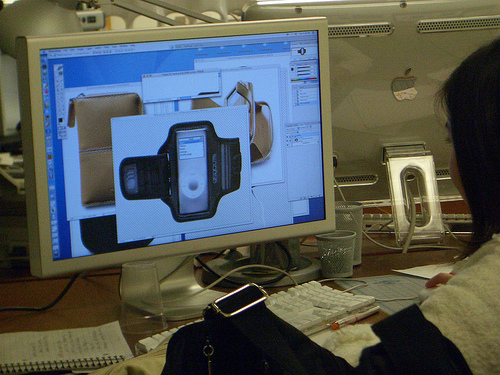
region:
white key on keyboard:
[318, 310, 330, 320]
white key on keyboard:
[327, 308, 341, 315]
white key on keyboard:
[331, 304, 343, 314]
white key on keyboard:
[298, 289, 310, 297]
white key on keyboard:
[308, 278, 320, 287]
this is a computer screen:
[29, 22, 438, 304]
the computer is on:
[42, 67, 250, 216]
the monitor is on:
[30, 44, 270, 245]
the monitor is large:
[37, 38, 316, 247]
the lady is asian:
[398, 87, 498, 253]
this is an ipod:
[102, 97, 253, 209]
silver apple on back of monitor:
[391, 67, 417, 101]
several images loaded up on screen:
[41, 28, 328, 258]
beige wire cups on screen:
[321, 194, 363, 280]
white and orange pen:
[330, 302, 382, 332]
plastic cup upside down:
[116, 259, 170, 336]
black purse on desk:
[158, 279, 350, 374]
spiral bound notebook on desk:
[0, 320, 134, 371]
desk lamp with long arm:
[1, 0, 228, 59]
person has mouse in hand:
[418, 270, 455, 304]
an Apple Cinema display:
[242, 3, 499, 247]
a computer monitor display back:
[240, 0, 497, 245]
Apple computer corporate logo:
[390, 68, 419, 101]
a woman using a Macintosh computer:
[17, 13, 497, 374]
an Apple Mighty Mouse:
[416, 284, 441, 302]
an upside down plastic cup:
[117, 260, 167, 336]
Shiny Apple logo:
[386, 66, 423, 103]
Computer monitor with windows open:
[28, 38, 337, 240]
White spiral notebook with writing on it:
[4, 327, 134, 368]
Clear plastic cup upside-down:
[108, 263, 165, 348]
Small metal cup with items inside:
[306, 227, 364, 276]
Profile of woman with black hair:
[439, 33, 497, 216]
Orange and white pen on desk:
[330, 303, 385, 332]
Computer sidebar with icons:
[33, 53, 70, 258]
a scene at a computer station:
[2, 3, 499, 371]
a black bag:
[125, 263, 365, 373]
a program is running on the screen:
[32, 36, 324, 253]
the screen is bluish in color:
[38, 24, 338, 251]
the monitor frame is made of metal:
[18, 13, 339, 282]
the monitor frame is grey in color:
[17, 12, 339, 281]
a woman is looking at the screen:
[375, 41, 496, 370]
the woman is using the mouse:
[419, 273, 454, 306]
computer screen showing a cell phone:
[18, 28, 357, 265]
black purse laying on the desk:
[164, 274, 339, 371]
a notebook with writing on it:
[7, 312, 156, 371]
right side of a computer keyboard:
[268, 270, 369, 333]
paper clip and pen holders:
[321, 195, 376, 272]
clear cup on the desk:
[111, 264, 183, 331]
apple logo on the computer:
[382, 58, 427, 109]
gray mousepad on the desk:
[353, 261, 425, 307]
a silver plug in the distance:
[61, 5, 114, 27]